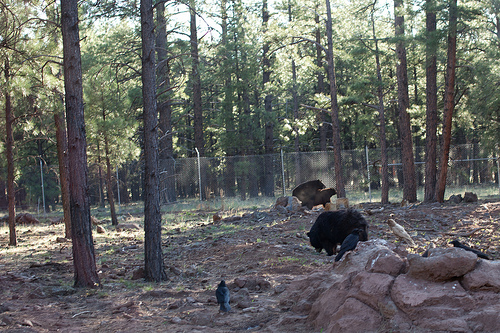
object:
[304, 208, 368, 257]
bear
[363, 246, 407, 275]
stone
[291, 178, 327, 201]
bear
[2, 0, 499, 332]
background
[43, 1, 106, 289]
tree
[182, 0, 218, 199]
tree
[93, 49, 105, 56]
leaf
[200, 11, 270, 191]
plant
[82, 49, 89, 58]
leaf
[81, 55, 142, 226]
plant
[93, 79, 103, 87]
leaf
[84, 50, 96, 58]
leaf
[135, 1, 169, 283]
tree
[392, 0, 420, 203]
tree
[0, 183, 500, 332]
field